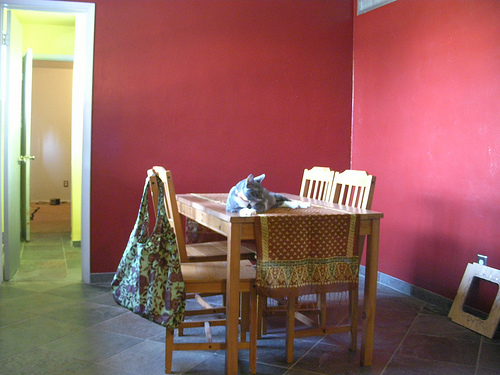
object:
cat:
[222, 168, 315, 220]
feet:
[239, 207, 258, 216]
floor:
[0, 226, 497, 371]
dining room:
[0, 2, 496, 373]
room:
[3, 4, 498, 372]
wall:
[94, 1, 351, 281]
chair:
[241, 164, 334, 328]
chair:
[260, 166, 377, 365]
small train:
[102, 164, 187, 327]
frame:
[1, 2, 96, 286]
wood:
[448, 256, 499, 337]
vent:
[357, 1, 393, 13]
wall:
[351, 0, 498, 330]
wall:
[9, 15, 79, 243]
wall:
[31, 67, 68, 204]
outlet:
[477, 252, 487, 264]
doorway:
[31, 59, 73, 241]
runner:
[254, 214, 374, 319]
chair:
[140, 162, 260, 374]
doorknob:
[26, 153, 36, 160]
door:
[23, 51, 35, 241]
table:
[166, 190, 381, 369]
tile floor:
[4, 261, 496, 373]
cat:
[225, 174, 311, 217]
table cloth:
[252, 209, 368, 297]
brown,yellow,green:
[259, 223, 357, 286]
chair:
[145, 167, 255, 371]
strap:
[135, 171, 175, 231]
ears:
[245, 173, 255, 188]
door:
[5, 10, 22, 280]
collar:
[239, 197, 249, 206]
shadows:
[224, 199, 496, 374]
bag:
[108, 166, 186, 327]